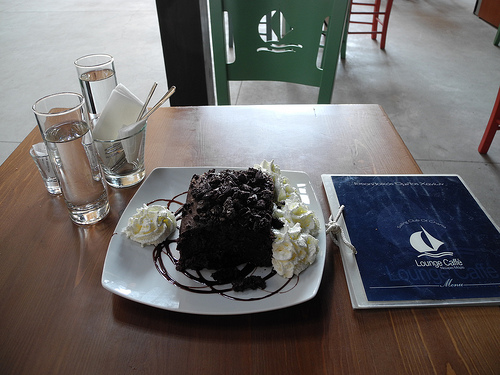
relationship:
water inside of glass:
[42, 120, 108, 208] [28, 88, 116, 230]